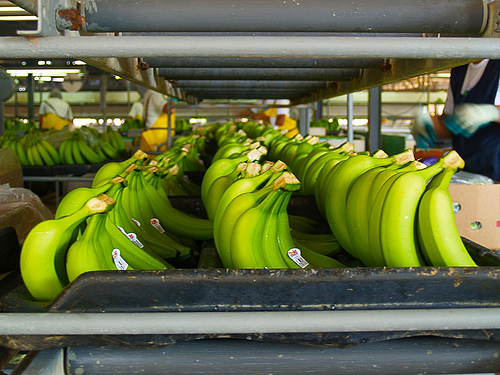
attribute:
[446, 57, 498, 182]
uniform — white , worker's blue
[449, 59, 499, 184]
vest — navy blue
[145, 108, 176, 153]
apron —  yellow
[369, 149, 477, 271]
bananas — many rows 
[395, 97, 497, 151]
gloves — white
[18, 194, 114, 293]
banana — yellow green 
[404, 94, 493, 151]
gloves — blue, white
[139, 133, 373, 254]
banana — yellow green 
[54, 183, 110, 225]
banana — yellow green 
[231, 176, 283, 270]
banana — yellow green 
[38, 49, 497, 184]
group —  worker's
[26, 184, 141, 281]
banana — bunches, sticks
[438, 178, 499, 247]
box — part, cardboard 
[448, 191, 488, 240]
bolts — two silver 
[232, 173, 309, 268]
banana bunch —  bunch , green 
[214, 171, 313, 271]
banana — yellow green 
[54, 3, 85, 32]
equipment — rusty 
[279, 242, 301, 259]
emblem — red , white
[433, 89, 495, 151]
gloves — blue , white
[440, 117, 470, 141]
fingertips — blue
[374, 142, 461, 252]
banana — v